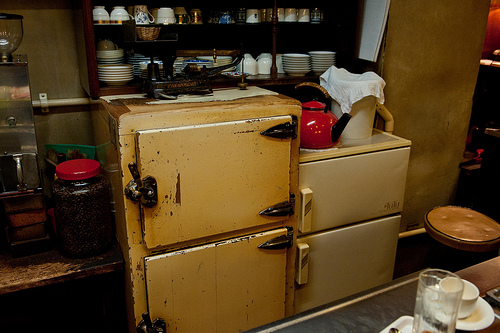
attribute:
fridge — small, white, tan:
[294, 130, 415, 327]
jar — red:
[44, 153, 124, 261]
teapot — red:
[288, 90, 350, 156]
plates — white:
[279, 46, 323, 80]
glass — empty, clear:
[405, 252, 472, 330]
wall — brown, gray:
[35, 26, 89, 93]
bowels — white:
[243, 46, 285, 73]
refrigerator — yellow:
[104, 93, 307, 332]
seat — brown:
[421, 192, 499, 251]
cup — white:
[435, 278, 484, 315]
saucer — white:
[413, 267, 496, 331]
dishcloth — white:
[322, 61, 393, 108]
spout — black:
[329, 109, 362, 147]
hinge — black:
[258, 118, 294, 147]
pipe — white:
[28, 90, 99, 112]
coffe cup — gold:
[95, 6, 139, 27]